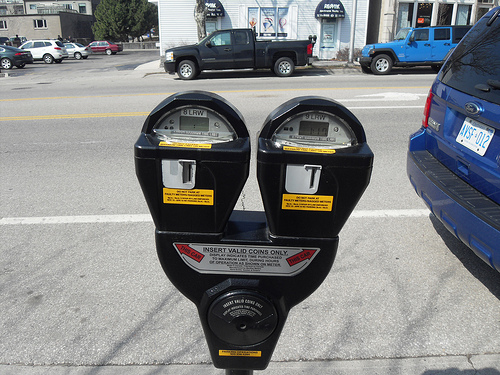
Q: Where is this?
A: This is at the street.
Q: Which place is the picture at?
A: It is at the street.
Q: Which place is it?
A: It is a street.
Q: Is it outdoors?
A: Yes, it is outdoors.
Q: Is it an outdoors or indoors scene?
A: It is outdoors.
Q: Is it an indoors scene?
A: No, it is outdoors.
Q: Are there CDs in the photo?
A: No, there are no cds.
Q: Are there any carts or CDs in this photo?
A: No, there are no CDs or carts.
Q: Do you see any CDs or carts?
A: No, there are no CDs or carts.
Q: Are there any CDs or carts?
A: No, there are no CDs or carts.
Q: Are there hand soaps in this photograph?
A: No, there are no hand soaps.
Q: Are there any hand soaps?
A: No, there are no hand soaps.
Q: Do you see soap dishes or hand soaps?
A: No, there are no hand soaps or soap dishes.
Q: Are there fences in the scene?
A: No, there are no fences.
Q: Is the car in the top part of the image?
A: Yes, the car is in the top of the image.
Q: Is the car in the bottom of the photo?
A: No, the car is in the top of the image.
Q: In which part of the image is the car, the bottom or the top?
A: The car is in the top of the image.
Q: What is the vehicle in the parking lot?
A: The vehicle is a car.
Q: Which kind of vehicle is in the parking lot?
A: The vehicle is a car.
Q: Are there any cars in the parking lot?
A: Yes, there is a car in the parking lot.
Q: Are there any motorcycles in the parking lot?
A: No, there is a car in the parking lot.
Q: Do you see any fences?
A: No, there are no fences.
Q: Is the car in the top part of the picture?
A: Yes, the car is in the top of the image.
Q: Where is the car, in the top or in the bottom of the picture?
A: The car is in the top of the image.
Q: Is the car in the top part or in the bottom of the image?
A: The car is in the top of the image.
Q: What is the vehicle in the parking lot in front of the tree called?
A: The vehicle is a car.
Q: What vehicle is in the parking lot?
A: The vehicle is a car.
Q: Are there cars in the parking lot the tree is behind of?
A: Yes, there is a car in the parking lot.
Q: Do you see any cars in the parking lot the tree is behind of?
A: Yes, there is a car in the parking lot.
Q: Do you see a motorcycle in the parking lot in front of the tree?
A: No, there is a car in the parking lot.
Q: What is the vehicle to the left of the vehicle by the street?
A: The vehicle is a car.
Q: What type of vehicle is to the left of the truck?
A: The vehicle is a car.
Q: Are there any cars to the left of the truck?
A: Yes, there is a car to the left of the truck.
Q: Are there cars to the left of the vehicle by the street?
A: Yes, there is a car to the left of the truck.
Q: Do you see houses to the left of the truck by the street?
A: No, there is a car to the left of the truck.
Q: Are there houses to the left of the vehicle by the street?
A: No, there is a car to the left of the truck.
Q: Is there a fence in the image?
A: No, there are no fences.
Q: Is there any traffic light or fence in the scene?
A: No, there are no fences or traffic lights.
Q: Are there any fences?
A: No, there are no fences.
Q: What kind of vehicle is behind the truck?
A: The vehicle is a car.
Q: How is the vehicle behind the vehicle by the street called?
A: The vehicle is a car.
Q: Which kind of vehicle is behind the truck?
A: The vehicle is a car.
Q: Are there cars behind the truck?
A: Yes, there is a car behind the truck.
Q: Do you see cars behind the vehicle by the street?
A: Yes, there is a car behind the truck.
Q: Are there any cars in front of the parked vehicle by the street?
A: No, the car is behind the truck.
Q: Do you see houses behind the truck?
A: No, there is a car behind the truck.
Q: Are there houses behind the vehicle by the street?
A: No, there is a car behind the truck.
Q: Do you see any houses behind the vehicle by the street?
A: No, there is a car behind the truck.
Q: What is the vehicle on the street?
A: The vehicle is a car.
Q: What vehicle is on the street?
A: The vehicle is a car.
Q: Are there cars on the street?
A: Yes, there is a car on the street.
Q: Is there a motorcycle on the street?
A: No, there is a car on the street.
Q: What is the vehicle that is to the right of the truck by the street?
A: The vehicle is a car.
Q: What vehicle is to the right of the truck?
A: The vehicle is a car.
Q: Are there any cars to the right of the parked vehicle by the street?
A: Yes, there is a car to the right of the truck.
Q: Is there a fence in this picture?
A: No, there are no fences.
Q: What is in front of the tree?
A: The parking lot is in front of the tree.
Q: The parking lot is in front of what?
A: The parking lot is in front of the tree.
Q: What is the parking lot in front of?
A: The parking lot is in front of the tree.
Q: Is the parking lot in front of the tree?
A: Yes, the parking lot is in front of the tree.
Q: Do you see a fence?
A: No, there are no fences.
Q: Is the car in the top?
A: Yes, the car is in the top of the image.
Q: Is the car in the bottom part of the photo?
A: No, the car is in the top of the image.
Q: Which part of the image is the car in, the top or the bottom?
A: The car is in the top of the image.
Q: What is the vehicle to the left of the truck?
A: The vehicle is a car.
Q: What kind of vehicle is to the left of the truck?
A: The vehicle is a car.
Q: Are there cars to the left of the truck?
A: Yes, there is a car to the left of the truck.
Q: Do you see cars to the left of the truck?
A: Yes, there is a car to the left of the truck.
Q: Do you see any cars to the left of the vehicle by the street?
A: Yes, there is a car to the left of the truck.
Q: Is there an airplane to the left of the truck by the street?
A: No, there is a car to the left of the truck.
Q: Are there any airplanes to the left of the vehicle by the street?
A: No, there is a car to the left of the truck.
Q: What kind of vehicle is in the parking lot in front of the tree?
A: The vehicle is a car.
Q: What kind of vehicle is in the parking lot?
A: The vehicle is a car.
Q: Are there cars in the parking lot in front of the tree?
A: Yes, there is a car in the parking lot.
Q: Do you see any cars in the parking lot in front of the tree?
A: Yes, there is a car in the parking lot.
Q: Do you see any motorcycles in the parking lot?
A: No, there is a car in the parking lot.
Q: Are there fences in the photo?
A: No, there are no fences.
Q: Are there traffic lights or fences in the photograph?
A: No, there are no fences or traffic lights.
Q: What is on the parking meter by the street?
A: The arrow is on the parking meter.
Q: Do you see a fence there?
A: No, there are no fences.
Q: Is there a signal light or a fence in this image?
A: No, there are no fences or traffic lights.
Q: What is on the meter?
A: The arrow is on the meter.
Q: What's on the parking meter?
A: The arrow is on the meter.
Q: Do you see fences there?
A: No, there are no fences.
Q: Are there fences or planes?
A: No, there are no fences or planes.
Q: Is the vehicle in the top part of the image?
A: Yes, the vehicle is in the top of the image.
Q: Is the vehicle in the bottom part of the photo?
A: No, the vehicle is in the top of the image.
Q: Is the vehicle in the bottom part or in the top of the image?
A: The vehicle is in the top of the image.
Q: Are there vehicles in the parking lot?
A: Yes, there is a vehicle in the parking lot.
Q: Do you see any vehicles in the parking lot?
A: Yes, there is a vehicle in the parking lot.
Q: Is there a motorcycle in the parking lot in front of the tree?
A: No, there is a vehicle in the parking lot.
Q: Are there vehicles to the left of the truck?
A: Yes, there is a vehicle to the left of the truck.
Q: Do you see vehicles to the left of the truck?
A: Yes, there is a vehicle to the left of the truck.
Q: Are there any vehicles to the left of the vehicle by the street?
A: Yes, there is a vehicle to the left of the truck.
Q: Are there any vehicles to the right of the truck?
A: No, the vehicle is to the left of the truck.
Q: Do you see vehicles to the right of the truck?
A: No, the vehicle is to the left of the truck.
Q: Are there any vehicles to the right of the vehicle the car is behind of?
A: No, the vehicle is to the left of the truck.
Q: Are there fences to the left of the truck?
A: No, there is a vehicle to the left of the truck.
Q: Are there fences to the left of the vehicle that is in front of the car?
A: No, there is a vehicle to the left of the truck.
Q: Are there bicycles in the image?
A: No, there are no bicycles.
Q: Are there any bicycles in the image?
A: No, there are no bicycles.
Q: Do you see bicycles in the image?
A: No, there are no bicycles.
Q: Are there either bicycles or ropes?
A: No, there are no bicycles or ropes.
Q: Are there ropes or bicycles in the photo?
A: No, there are no bicycles or ropes.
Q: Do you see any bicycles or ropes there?
A: No, there are no bicycles or ropes.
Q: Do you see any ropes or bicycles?
A: No, there are no bicycles or ropes.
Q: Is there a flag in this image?
A: No, there are no flags.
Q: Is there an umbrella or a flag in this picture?
A: No, there are no flags or umbrellas.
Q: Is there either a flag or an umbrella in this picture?
A: No, there are no flags or umbrellas.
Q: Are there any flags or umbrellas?
A: No, there are no flags or umbrellas.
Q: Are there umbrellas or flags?
A: No, there are no flags or umbrellas.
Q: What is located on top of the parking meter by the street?
A: The sticker is on top of the parking meter.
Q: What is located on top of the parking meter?
A: The sticker is on top of the parking meter.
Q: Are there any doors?
A: Yes, there is a door.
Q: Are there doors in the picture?
A: Yes, there is a door.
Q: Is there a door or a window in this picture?
A: Yes, there is a door.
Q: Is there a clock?
A: No, there are no clocks.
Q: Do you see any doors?
A: Yes, there is a door.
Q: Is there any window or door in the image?
A: Yes, there is a door.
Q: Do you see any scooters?
A: No, there are no scooters.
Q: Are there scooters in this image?
A: No, there are no scooters.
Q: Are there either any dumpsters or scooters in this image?
A: No, there are no scooters or dumpsters.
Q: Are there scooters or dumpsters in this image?
A: No, there are no scooters or dumpsters.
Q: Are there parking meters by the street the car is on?
A: Yes, there is a parking meter by the street.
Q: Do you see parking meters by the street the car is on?
A: Yes, there is a parking meter by the street.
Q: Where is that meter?
A: The meter is on the street.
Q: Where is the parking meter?
A: The meter is on the street.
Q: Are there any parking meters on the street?
A: Yes, there is a parking meter on the street.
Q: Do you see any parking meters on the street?
A: Yes, there is a parking meter on the street.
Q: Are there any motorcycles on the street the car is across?
A: No, there is a parking meter on the street.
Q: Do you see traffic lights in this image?
A: No, there are no traffic lights.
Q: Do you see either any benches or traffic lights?
A: No, there are no traffic lights or benches.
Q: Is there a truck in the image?
A: Yes, there is a truck.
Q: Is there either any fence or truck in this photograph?
A: Yes, there is a truck.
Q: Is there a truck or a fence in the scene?
A: Yes, there is a truck.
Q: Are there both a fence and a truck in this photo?
A: No, there is a truck but no fences.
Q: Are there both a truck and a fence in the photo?
A: No, there is a truck but no fences.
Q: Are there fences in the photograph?
A: No, there are no fences.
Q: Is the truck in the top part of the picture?
A: Yes, the truck is in the top of the image.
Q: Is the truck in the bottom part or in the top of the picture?
A: The truck is in the top of the image.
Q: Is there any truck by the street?
A: Yes, there is a truck by the street.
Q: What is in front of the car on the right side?
A: The truck is in front of the car.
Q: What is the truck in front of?
A: The truck is in front of the car.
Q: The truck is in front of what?
A: The truck is in front of the car.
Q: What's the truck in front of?
A: The truck is in front of the car.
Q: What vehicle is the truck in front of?
A: The truck is in front of the car.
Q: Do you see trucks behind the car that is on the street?
A: No, the truck is in front of the car.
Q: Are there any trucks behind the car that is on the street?
A: No, the truck is in front of the car.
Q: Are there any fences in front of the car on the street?
A: No, there is a truck in front of the car.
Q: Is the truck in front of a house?
A: No, the truck is in front of the car.